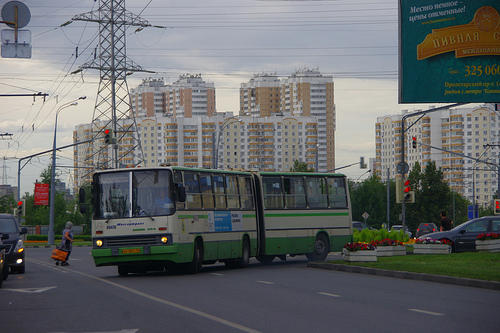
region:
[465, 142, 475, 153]
window on side of building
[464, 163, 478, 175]
window on side of building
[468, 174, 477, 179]
window on side of building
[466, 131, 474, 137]
window on side of building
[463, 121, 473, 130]
window on side of building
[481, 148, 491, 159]
window on side of building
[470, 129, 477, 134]
window on side of building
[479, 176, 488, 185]
window on side of building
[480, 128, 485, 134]
window on side of building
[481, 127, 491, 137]
window on side of building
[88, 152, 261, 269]
White and green bus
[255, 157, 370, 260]
White and green bus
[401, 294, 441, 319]
White line on the pavement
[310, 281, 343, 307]
White line on the pavement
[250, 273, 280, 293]
White line on the pavement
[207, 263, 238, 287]
White line on the pavement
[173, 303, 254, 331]
White line on the pavement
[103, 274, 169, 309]
White line on the pavement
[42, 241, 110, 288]
White line on the pavement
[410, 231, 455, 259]
White flower pot on grass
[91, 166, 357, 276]
bus turns corner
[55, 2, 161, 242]
power lines are behind bus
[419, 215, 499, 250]
car waits for bus to make the turn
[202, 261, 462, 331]
dotted line divides the street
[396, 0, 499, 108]
billboard advertises a product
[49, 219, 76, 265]
human crosses the street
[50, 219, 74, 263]
human tows something behind them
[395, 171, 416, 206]
traffic light signals for people to stop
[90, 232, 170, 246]
bus headlights are on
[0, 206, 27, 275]
vehicle headlights are on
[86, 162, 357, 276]
the bus is green and white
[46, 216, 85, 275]
a person is walking on the road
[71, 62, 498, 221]
the buildings are brown and white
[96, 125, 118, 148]
the traffic light is red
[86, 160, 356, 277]
the bus is long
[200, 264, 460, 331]
the road has white dashed lines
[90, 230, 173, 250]
the bus's headlights are on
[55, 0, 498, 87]
power lines above the bus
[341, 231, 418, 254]
the flowers are red and yellow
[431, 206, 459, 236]
a man in a black shirt is standing by the car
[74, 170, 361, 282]
the bus on the street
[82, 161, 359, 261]
the bus is turning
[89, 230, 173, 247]
the lights on the bus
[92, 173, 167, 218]
the windshield of the bus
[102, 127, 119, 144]
the red traffic light above the bus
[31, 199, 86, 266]
the person crossing the street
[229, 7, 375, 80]
the clouds in the sky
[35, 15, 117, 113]
power lines above the street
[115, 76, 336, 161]
the buildings are tan